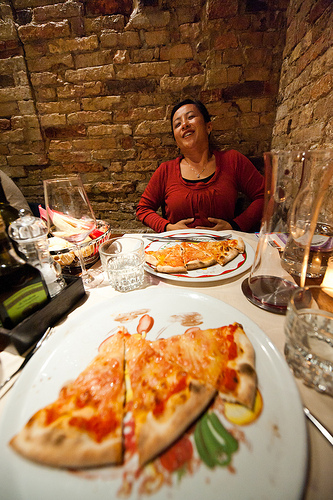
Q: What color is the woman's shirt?
A: Red.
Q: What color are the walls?
A: Brown.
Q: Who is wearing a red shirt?
A: The woman.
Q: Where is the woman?
A: Behind the table.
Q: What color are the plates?
A: White.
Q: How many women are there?
A: One.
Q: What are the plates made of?
A: Porcelain.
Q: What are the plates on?
A: The table.